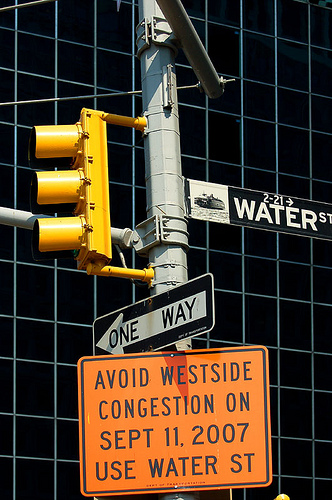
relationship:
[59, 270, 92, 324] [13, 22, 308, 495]
window on building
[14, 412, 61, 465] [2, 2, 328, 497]
window on building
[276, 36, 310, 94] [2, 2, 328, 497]
window on building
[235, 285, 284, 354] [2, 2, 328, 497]
window on building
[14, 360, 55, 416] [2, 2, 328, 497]
window on building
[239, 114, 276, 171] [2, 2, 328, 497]
window on building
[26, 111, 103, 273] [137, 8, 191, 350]
signal on pole